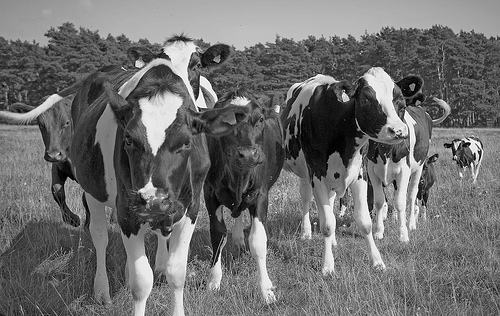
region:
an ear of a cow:
[198, 101, 253, 140]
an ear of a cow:
[201, 42, 233, 69]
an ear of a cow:
[330, 76, 357, 108]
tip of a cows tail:
[1, 104, 41, 131]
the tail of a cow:
[424, 86, 452, 133]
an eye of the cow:
[173, 133, 199, 155]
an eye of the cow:
[115, 131, 142, 152]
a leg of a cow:
[244, 214, 281, 300]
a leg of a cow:
[309, 185, 340, 265]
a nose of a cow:
[129, 187, 178, 221]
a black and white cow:
[442, 135, 486, 185]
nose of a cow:
[131, 190, 172, 215]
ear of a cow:
[191, 108, 251, 138]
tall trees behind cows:
[0, 21, 499, 121]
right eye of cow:
[121, 131, 136, 146]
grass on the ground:
[346, 283, 437, 304]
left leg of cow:
[243, 202, 275, 303]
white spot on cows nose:
[135, 171, 161, 197]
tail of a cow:
[425, 92, 450, 123]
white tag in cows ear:
[132, 54, 148, 68]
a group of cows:
[0, 22, 479, 297]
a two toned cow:
[265, 45, 426, 287]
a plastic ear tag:
[203, 45, 232, 72]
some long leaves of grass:
[395, 241, 495, 308]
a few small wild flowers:
[430, 194, 465, 236]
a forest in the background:
[7, 17, 497, 149]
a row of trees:
[236, 20, 495, 130]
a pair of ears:
[88, 77, 257, 144]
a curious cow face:
[201, 77, 288, 181]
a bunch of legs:
[296, 187, 453, 279]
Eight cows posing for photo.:
[25, 32, 495, 308]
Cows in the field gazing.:
[20, 42, 494, 307]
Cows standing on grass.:
[10, 35, 475, 300]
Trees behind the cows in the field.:
[0, 20, 495, 115]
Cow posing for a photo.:
[75, 70, 215, 310]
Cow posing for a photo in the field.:
[290, 65, 405, 285]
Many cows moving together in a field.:
[6, 45, 486, 305]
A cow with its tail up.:
[0, 50, 200, 310]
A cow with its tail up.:
[380, 80, 445, 240]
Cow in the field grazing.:
[207, 86, 285, 306]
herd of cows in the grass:
[26, 36, 481, 303]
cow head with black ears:
[333, 57, 437, 157]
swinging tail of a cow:
[7, 94, 107, 125]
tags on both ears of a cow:
[116, 34, 242, 76]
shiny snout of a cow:
[121, 179, 191, 234]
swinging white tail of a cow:
[429, 88, 457, 134]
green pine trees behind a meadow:
[247, 39, 309, 84]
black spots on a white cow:
[279, 83, 329, 160]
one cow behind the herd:
[442, 130, 494, 204]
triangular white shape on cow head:
[134, 91, 190, 164]